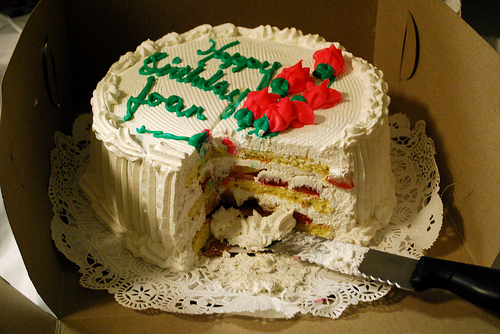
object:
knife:
[261, 233, 499, 319]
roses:
[306, 45, 344, 80]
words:
[120, 76, 205, 118]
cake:
[79, 21, 394, 273]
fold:
[0, 36, 105, 310]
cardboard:
[0, 0, 499, 333]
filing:
[166, 133, 350, 265]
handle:
[409, 257, 500, 318]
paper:
[39, 111, 175, 317]